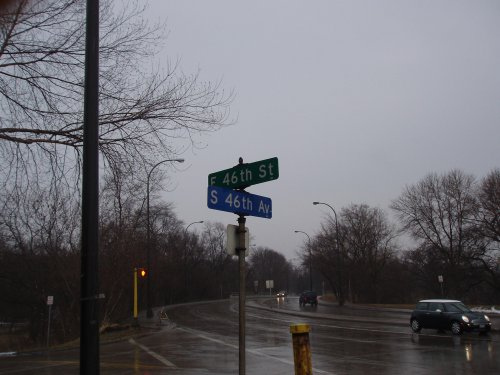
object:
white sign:
[46, 296, 53, 306]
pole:
[46, 305, 51, 347]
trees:
[294, 168, 499, 308]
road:
[163, 294, 499, 373]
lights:
[277, 293, 285, 295]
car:
[409, 298, 493, 335]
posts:
[294, 201, 343, 302]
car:
[276, 291, 288, 297]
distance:
[8, 7, 498, 319]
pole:
[288, 322, 313, 375]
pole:
[78, 1, 100, 375]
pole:
[236, 216, 248, 375]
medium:
[245, 293, 412, 328]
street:
[1, 292, 499, 375]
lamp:
[138, 268, 149, 281]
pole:
[133, 268, 138, 319]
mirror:
[435, 309, 442, 313]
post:
[440, 282, 444, 298]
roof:
[418, 299, 462, 303]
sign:
[205, 155, 280, 374]